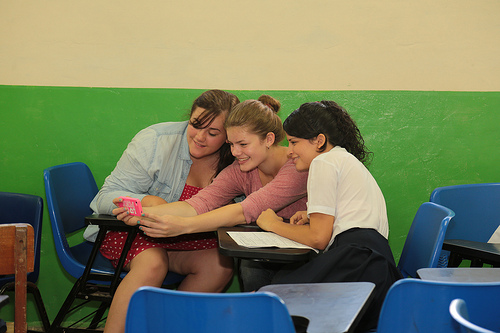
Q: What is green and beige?
A: The wall.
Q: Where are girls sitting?
A: On chairs.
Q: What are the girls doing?
A: Taking a selfie.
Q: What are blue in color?
A: Chairs.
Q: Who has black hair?
A: Girl on right.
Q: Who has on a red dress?
A: Girl on left.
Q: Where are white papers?
A: On the desk.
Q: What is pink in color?
A: Cell phone.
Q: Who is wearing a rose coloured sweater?
A: Girl in the middle.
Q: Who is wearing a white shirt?
A: Girl on the right.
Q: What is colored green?
A: The wall.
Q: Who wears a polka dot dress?
A: Woman on the left.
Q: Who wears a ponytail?
A: Woman on the right.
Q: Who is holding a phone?
A: Woman in the middle.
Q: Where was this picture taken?
A: In a classroom.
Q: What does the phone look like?
A: Pink.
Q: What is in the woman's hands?
A: Phone.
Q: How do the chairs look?
A: Blue.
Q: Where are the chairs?
A: At the desks.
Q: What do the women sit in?
A: Chairs.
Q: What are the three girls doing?
A: Posing for a camera.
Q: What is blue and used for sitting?
A: The chair.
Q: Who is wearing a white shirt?
A: The young girl.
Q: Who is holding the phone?
A: A young girl.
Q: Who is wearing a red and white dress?
A: The young girl.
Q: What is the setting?
A: A classroom.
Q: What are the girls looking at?
A: A cell phone.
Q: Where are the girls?
A: School.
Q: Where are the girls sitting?
A: School desks.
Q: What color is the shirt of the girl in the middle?
A: Pink.